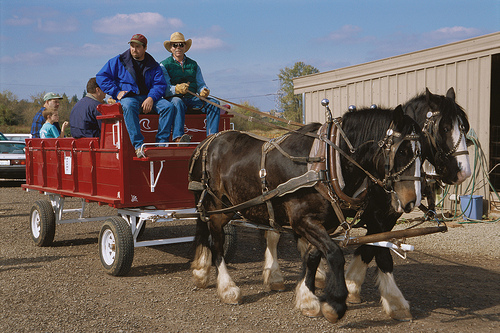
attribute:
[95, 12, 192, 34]
cloud — white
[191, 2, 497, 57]
sky — blue 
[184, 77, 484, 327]
horses — brown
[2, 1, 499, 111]
sky — bright blue